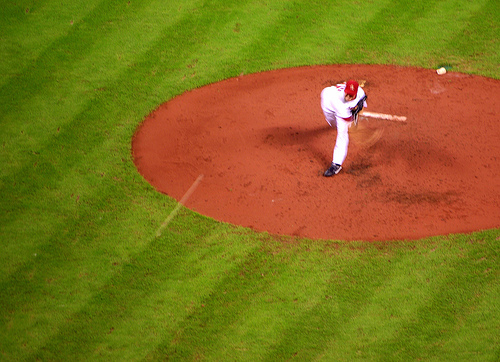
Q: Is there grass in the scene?
A: Yes, there is grass.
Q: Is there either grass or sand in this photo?
A: Yes, there is grass.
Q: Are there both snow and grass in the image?
A: No, there is grass but no snow.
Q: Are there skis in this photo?
A: No, there are no skis.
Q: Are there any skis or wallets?
A: No, there are no skis or wallets.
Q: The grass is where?
A: The grass is on the ground.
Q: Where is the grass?
A: The grass is on the ground.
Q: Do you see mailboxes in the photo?
A: No, there are no mailboxes.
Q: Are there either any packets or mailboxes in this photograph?
A: No, there are no mailboxes or packets.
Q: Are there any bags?
A: No, there are no bags.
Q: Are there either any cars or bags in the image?
A: No, there are no bags or cars.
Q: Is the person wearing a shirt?
A: Yes, the person is wearing a shirt.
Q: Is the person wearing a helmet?
A: No, the person is wearing a shirt.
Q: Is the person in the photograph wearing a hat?
A: Yes, the person is wearing a hat.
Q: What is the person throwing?
A: The person is throwing the ball.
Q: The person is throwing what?
A: The person is throwing the ball.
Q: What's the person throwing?
A: The person is throwing the ball.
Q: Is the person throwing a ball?
A: Yes, the person is throwing a ball.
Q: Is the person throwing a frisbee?
A: No, the person is throwing a ball.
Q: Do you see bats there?
A: Yes, there is a bat.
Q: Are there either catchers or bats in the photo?
A: Yes, there is a bat.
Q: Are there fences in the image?
A: No, there are no fences.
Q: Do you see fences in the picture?
A: No, there are no fences.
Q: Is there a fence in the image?
A: No, there are no fences.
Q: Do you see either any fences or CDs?
A: No, there are no fences or cds.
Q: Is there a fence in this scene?
A: No, there are no fences.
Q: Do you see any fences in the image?
A: No, there are no fences.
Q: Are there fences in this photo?
A: No, there are no fences.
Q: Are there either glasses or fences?
A: No, there are no fences or glasses.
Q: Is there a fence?
A: No, there are no fences.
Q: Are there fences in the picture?
A: No, there are no fences.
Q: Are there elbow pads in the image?
A: No, there are no elbow pads.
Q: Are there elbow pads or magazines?
A: No, there are no elbow pads or magazines.